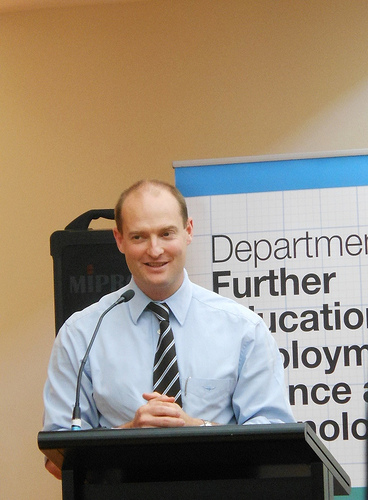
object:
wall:
[0, 0, 368, 500]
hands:
[121, 395, 185, 429]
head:
[113, 177, 194, 288]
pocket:
[182, 375, 236, 425]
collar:
[127, 268, 193, 326]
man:
[40, 177, 297, 432]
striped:
[152, 302, 181, 402]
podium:
[37, 423, 350, 500]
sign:
[171, 147, 368, 500]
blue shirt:
[42, 266, 297, 432]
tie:
[146, 301, 183, 408]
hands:
[142, 392, 195, 428]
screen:
[182, 185, 367, 487]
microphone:
[70, 289, 135, 432]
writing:
[212, 230, 368, 440]